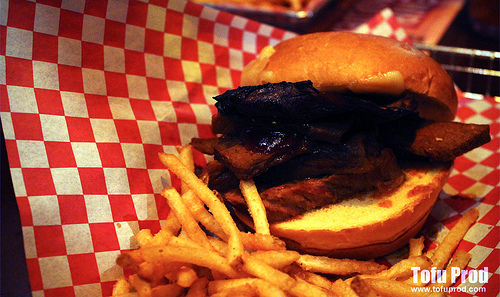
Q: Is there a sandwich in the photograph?
A: Yes, there is a sandwich.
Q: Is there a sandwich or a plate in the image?
A: Yes, there is a sandwich.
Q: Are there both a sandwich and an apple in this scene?
A: No, there is a sandwich but no apples.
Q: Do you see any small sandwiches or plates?
A: Yes, there is a small sandwich.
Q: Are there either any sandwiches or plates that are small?
A: Yes, the sandwich is small.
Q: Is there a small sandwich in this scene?
A: Yes, there is a small sandwich.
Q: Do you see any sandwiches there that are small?
A: Yes, there is a sandwich that is small.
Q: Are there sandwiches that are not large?
A: Yes, there is a small sandwich.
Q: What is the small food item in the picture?
A: The food item is a sandwich.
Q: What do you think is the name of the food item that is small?
A: The food item is a sandwich.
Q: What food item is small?
A: The food item is a sandwich.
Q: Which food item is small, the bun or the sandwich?
A: The sandwich is small.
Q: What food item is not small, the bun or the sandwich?
A: The bun is not small.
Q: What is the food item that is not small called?
A: The food item is a bun.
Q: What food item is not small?
A: The food item is a bun.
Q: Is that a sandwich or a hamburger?
A: That is a sandwich.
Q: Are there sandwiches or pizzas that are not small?
A: No, there is a sandwich but it is small.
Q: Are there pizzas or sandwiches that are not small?
A: No, there is a sandwich but it is small.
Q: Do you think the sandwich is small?
A: Yes, the sandwich is small.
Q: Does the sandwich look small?
A: Yes, the sandwich is small.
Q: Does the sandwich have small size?
A: Yes, the sandwich is small.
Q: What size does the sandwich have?
A: The sandwich has small size.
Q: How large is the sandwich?
A: The sandwich is small.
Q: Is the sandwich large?
A: No, the sandwich is small.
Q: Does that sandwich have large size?
A: No, the sandwich is small.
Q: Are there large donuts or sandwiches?
A: No, there is a sandwich but it is small.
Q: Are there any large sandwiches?
A: No, there is a sandwich but it is small.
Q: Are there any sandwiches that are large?
A: No, there is a sandwich but it is small.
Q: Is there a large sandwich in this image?
A: No, there is a sandwich but it is small.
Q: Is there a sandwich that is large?
A: No, there is a sandwich but it is small.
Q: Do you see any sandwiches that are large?
A: No, there is a sandwich but it is small.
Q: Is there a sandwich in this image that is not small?
A: No, there is a sandwich but it is small.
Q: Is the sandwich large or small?
A: The sandwich is small.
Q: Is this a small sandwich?
A: Yes, this is a small sandwich.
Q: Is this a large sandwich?
A: No, this is a small sandwich.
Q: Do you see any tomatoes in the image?
A: No, there are no tomatoes.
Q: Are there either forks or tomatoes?
A: No, there are no tomatoes or forks.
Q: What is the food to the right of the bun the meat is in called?
A: The food is fries.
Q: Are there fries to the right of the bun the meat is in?
A: Yes, there are fries to the right of the bun.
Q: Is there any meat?
A: Yes, there is meat.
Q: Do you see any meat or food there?
A: Yes, there is meat.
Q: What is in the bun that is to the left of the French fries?
A: The meat is in the bun.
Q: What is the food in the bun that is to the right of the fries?
A: The food is meat.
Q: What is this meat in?
A: The meat is in the bun.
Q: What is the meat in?
A: The meat is in the bun.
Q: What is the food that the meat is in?
A: The food is a bun.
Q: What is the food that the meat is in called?
A: The food is a bun.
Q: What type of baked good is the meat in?
A: The meat is in the bun.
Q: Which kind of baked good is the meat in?
A: The meat is in the bun.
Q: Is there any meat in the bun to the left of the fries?
A: Yes, there is meat in the bun.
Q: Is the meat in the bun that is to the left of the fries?
A: Yes, the meat is in the bun.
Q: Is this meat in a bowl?
A: No, the meat is in the bun.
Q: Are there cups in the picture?
A: No, there are no cups.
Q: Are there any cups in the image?
A: No, there are no cups.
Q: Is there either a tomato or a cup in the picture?
A: No, there are no cups or tomatoes.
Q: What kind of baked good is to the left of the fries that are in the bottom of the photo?
A: The food is a bun.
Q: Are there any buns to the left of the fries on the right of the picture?
A: Yes, there is a bun to the left of the fries.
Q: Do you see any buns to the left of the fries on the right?
A: Yes, there is a bun to the left of the fries.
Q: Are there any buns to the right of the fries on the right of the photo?
A: No, the bun is to the left of the fries.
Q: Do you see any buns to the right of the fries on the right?
A: No, the bun is to the left of the fries.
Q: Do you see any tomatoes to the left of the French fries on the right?
A: No, there is a bun to the left of the French fries.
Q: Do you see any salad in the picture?
A: No, there is no salad.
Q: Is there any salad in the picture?
A: No, there is no salad.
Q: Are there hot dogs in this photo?
A: No, there are no hot dogs.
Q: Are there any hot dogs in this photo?
A: No, there are no hot dogs.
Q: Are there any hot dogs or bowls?
A: No, there are no hot dogs or bowls.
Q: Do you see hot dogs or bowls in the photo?
A: No, there are no hot dogs or bowls.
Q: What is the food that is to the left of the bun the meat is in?
A: The food is fries.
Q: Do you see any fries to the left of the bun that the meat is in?
A: Yes, there are fries to the left of the bun.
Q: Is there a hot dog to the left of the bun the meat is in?
A: No, there are fries to the left of the bun.